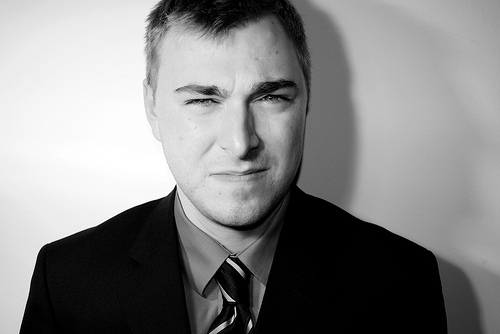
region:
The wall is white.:
[78, 35, 109, 121]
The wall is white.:
[58, 95, 172, 237]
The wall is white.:
[87, 78, 133, 155]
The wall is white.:
[54, 63, 106, 143]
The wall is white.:
[74, 115, 121, 197]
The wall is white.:
[67, 106, 107, 181]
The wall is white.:
[78, 78, 160, 188]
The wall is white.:
[33, 43, 108, 178]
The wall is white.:
[108, 56, 153, 161]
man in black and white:
[67, 4, 436, 311]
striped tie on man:
[204, 249, 271, 329]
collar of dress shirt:
[173, 224, 282, 292]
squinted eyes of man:
[176, 73, 303, 116]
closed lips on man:
[197, 155, 280, 193]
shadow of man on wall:
[292, 23, 366, 207]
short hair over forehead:
[176, 8, 235, 50]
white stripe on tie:
[217, 255, 255, 281]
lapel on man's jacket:
[125, 203, 177, 277]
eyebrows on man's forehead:
[179, 68, 294, 100]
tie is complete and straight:
[212, 251, 252, 332]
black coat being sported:
[16, 185, 448, 331]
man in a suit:
[25, 1, 451, 330]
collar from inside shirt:
[172, 185, 297, 296]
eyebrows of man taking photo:
[174, 75, 299, 90]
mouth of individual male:
[207, 163, 272, 182]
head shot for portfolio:
[140, 3, 314, 230]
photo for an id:
[142, 0, 312, 226]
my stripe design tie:
[207, 250, 257, 331]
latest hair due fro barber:
[142, 2, 314, 89]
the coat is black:
[51, 224, 431, 332]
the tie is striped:
[204, 256, 252, 327]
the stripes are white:
[215, 258, 256, 330]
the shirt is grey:
[171, 218, 266, 317]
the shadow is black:
[315, 103, 362, 195]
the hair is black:
[173, 9, 273, 30]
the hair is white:
[138, 27, 165, 72]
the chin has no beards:
[204, 188, 274, 220]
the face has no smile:
[158, 53, 292, 215]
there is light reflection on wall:
[57, 85, 168, 189]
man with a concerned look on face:
[127, 2, 363, 243]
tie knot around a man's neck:
[201, 247, 271, 321]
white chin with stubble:
[201, 187, 278, 232]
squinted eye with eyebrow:
[167, 74, 230, 114]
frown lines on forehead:
[221, 70, 265, 103]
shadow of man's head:
[306, 7, 396, 191]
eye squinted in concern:
[247, 72, 309, 117]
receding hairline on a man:
[170, 15, 301, 47]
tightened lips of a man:
[205, 162, 282, 187]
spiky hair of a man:
[136, 7, 177, 97]